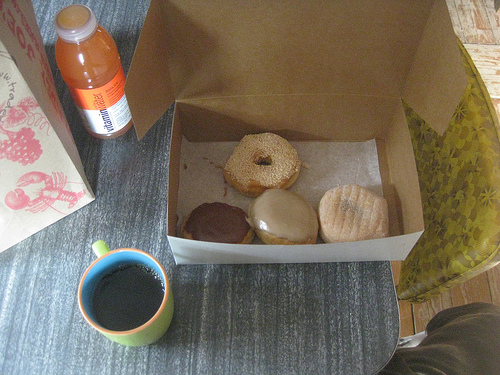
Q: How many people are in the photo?
A: Zero.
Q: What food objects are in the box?
A: Doughnuts.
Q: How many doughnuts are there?
A: Four.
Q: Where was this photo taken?
A: Kitchen table.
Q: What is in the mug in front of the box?
A: Coffee.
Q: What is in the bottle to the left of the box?
A: Vitamin Water.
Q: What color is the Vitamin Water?
A: Orange.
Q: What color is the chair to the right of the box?
A: Green.